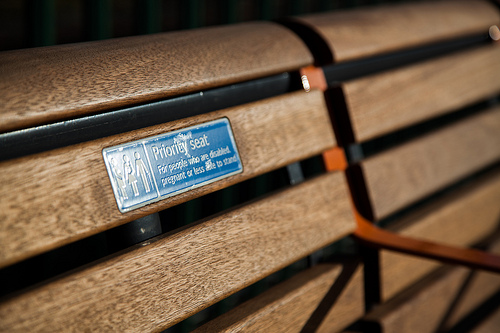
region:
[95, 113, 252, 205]
Sign on a park bench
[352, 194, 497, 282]
Armrest on a park bench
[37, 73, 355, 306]
Slats on a park bench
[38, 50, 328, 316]
Backrest on a park bench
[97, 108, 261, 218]
Sign for disabled people on the park bench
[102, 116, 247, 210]
Sign for pregnant women on the park bench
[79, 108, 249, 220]
Priority seat sign on the park bench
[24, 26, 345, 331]
Area reserved for disabled people on a park bench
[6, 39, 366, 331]
Area reserved for pregnant women on a park bench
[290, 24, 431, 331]
Joint between two park benches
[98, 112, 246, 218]
small blue and white sign in a bench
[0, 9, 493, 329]
brown wooden backplate of a bench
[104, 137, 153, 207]
drawing of three people on a blue sign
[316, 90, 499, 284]
brown wooden handrails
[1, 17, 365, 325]
four wooden stumps in the backplate in the left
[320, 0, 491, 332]
five brow wooden stumps in the backplate in the right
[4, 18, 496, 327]
wooden brown bench for disabled people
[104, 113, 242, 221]
priority seat blue signboard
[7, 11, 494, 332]
two backplates of a priority seats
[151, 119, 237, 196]
white letters in a blue sign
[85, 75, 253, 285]
a sign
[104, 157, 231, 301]
a sign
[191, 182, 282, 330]
a sign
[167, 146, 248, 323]
a sign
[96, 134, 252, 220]
blue sign with white letters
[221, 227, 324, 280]
1 wooden bench slat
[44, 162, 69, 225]
wooden bench slat with sign on it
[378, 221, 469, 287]
armrest of wooden bench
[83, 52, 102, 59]
curved wooden bench slat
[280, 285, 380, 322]
shadow cast on bench slat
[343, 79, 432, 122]
blurred wooden bench slat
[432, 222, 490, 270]
another wooden bench slat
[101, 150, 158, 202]
logo for people on sign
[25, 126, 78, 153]
black background behind bench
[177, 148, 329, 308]
a sign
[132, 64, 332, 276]
a sign